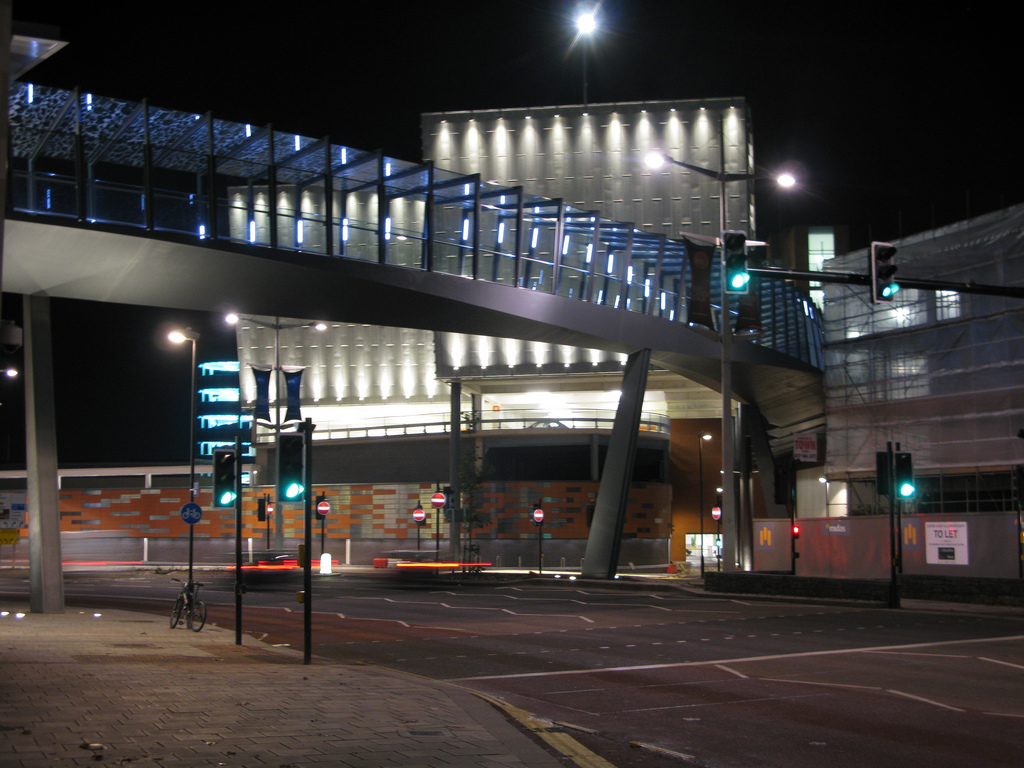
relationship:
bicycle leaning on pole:
[163, 573, 211, 635] [177, 529, 198, 631]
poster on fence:
[915, 516, 973, 584] [966, 507, 1015, 575]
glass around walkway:
[38, 157, 702, 303] [14, 68, 837, 462]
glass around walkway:
[763, 292, 825, 354] [14, 68, 837, 462]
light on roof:
[564, 5, 612, 103] [406, 87, 738, 120]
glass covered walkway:
[759, 272, 827, 372] [8, 83, 834, 437]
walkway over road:
[8, 83, 834, 437] [77, 568, 251, 595]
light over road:
[895, 479, 921, 504] [210, 557, 1008, 731]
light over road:
[281, 478, 310, 504] [67, 557, 188, 625]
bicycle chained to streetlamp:
[157, 566, 211, 637] [157, 320, 214, 624]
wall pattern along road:
[2, 482, 26, 571] [201, 566, 689, 678]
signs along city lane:
[696, 498, 719, 530] [0, 558, 1023, 764]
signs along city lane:
[403, 504, 427, 525] [0, 558, 1023, 764]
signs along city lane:
[421, 489, 453, 515] [0, 558, 1023, 764]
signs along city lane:
[519, 501, 549, 524] [0, 558, 1023, 764]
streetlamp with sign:
[168, 329, 211, 643] [166, 495, 205, 531]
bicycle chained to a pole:
[163, 573, 211, 635] [176, 327, 197, 631]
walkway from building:
[8, 83, 852, 438] [775, 222, 846, 292]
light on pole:
[206, 440, 239, 517] [756, 261, 867, 285]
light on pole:
[883, 447, 922, 504] [882, 497, 914, 618]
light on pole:
[263, 408, 311, 510] [882, 497, 917, 603]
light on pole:
[713, 223, 765, 303] [746, 264, 860, 293]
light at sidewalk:
[214, 484, 240, 509] [11, 615, 243, 657]